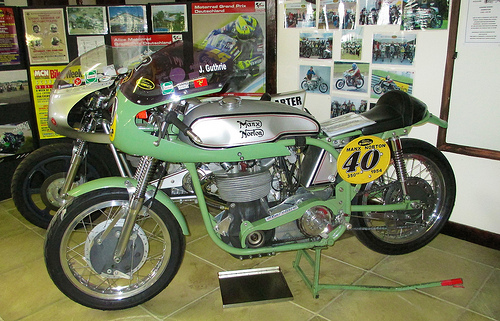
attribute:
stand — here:
[306, 256, 470, 306]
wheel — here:
[345, 125, 484, 275]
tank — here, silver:
[210, 164, 293, 207]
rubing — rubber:
[52, 190, 129, 218]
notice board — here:
[290, 8, 438, 173]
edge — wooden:
[428, 17, 459, 163]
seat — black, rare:
[306, 68, 423, 137]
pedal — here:
[297, 223, 366, 242]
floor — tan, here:
[199, 245, 219, 287]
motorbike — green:
[53, 16, 464, 252]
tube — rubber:
[47, 194, 159, 235]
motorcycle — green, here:
[90, 39, 448, 282]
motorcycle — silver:
[23, 23, 119, 209]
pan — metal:
[208, 256, 295, 305]